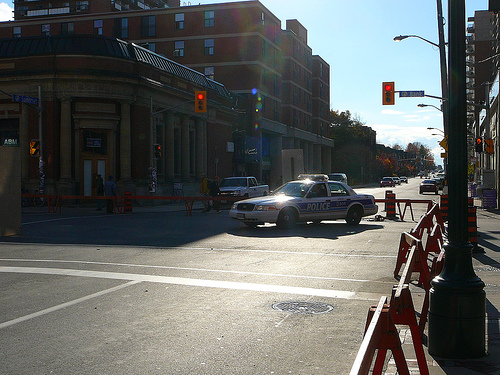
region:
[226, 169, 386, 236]
THIS IS A POLICE CAR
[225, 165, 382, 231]
THE CAR IS WHITE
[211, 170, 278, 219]
THE TRUCK IS WHITE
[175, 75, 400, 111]
THE TRAFFIC LIGHTS ARE RED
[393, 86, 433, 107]
THE SIGN IS ABOVE THE COP CAR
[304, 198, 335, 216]
THE SIDE OF THE CAR SAYS POLICE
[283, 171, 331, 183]
THE CAR HAS LIGHTS ON TOP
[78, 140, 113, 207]
THIS IS A DOOR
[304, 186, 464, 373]
THIS IS A BARACADE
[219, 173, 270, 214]
THE TRUCK IS PARKED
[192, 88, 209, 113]
This is a traffic signal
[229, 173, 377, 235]
Police patrol car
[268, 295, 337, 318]
This is a manhole cover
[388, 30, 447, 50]
This is a street light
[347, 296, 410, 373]
This is a traffic barrier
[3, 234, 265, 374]
this is street pavment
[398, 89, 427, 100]
This is a street sign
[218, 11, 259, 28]
This is a brick wall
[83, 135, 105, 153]
This is a business sign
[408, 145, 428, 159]
This is a tree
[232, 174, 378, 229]
a police car parked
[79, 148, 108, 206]
wood and glass doors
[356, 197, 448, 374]
emergency barriers outside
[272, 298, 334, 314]
a manhole in the ground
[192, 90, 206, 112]
a streetlight showing red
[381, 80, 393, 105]
a streetlight showing red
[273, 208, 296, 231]
front tire of a car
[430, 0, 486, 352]
a tall metal pole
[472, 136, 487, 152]
a streetlight showing red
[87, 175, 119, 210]
people standing at a distance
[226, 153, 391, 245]
a police car on the road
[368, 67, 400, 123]
the stop light is red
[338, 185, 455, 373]
a barricade on the road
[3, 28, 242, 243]
a building on the corner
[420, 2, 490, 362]
a black pole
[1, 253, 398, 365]
white lines on the road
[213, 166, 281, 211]
a parked white truck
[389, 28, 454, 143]
a row of street lights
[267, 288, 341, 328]
a man hole cover on the road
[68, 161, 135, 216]
people are standing on the sidewalk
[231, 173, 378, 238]
A police car acting as a roadblock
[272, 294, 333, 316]
A man hole cover in the road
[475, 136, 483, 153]
A crosswalk light that is red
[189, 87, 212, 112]
A traffic light that is red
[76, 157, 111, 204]
A doubled sided door into a building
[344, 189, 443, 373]
Orange barricades set up in the street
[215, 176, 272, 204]
A white pickup truck parked on the street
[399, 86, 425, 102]
A blue sign street on a pole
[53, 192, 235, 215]
Orange barricades blocking the street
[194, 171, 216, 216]
A man in a yellow top walking.